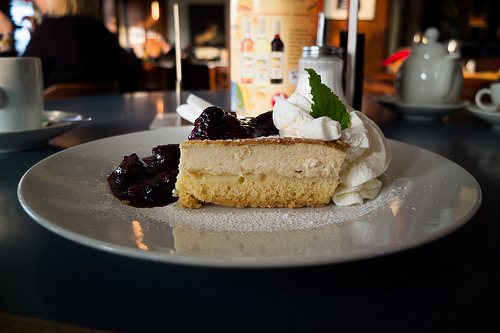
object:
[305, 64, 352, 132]
mint leaf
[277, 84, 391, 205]
whipped cream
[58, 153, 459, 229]
powdered sugar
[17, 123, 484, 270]
dish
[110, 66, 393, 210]
dessert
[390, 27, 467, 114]
tea kettle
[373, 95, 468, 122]
dish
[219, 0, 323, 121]
menu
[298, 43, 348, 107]
sugar jar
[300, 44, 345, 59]
cap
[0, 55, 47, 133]
coffe mug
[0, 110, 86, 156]
dish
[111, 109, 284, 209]
fruit topping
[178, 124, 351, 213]
cake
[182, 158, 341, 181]
cream filling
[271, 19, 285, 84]
wine bottles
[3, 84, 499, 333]
table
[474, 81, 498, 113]
tea cup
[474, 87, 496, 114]
handle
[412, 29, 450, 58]
lid